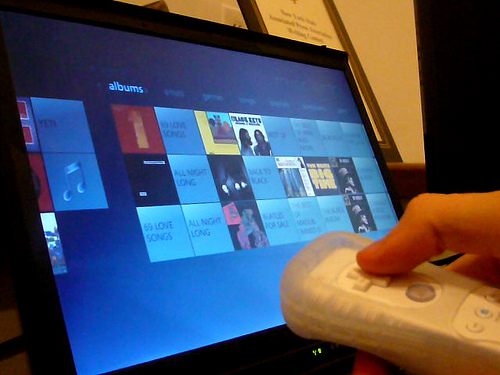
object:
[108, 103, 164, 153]
albums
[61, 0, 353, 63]
rim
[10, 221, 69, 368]
rim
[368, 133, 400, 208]
rim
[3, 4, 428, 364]
television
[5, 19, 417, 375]
screen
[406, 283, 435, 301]
button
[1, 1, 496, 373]
indoors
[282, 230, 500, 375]
remote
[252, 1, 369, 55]
frame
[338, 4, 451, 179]
wall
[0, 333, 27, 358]
cord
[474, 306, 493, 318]
button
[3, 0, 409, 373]
computer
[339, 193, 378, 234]
picture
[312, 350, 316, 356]
indicator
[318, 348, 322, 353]
indicator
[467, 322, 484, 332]
button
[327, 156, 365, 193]
square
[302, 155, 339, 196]
square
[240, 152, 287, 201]
square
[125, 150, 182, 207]
square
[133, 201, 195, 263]
square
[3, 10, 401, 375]
screen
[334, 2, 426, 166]
wall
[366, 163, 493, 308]
thumb